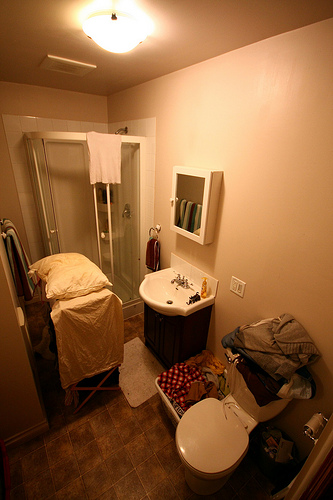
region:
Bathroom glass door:
[115, 220, 131, 258]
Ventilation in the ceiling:
[48, 58, 81, 74]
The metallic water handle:
[120, 204, 130, 220]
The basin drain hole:
[167, 298, 172, 304]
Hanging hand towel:
[146, 238, 157, 269]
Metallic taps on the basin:
[170, 271, 188, 289]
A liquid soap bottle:
[201, 278, 206, 297]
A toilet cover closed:
[187, 414, 226, 453]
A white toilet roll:
[310, 417, 323, 426]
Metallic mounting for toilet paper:
[306, 432, 315, 441]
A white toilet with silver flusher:
[175, 343, 293, 497]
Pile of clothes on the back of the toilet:
[221, 314, 321, 406]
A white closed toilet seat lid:
[175, 396, 250, 474]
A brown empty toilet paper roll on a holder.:
[304, 408, 327, 437]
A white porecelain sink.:
[138, 262, 213, 314]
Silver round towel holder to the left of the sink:
[145, 224, 162, 239]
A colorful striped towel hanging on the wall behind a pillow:
[1, 217, 40, 299]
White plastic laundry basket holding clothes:
[152, 377, 188, 427]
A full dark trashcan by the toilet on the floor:
[258, 425, 297, 481]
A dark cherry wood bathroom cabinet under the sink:
[141, 302, 212, 369]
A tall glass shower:
[22, 130, 146, 319]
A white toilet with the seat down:
[174, 345, 293, 496]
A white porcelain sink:
[140, 267, 216, 315]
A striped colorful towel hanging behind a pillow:
[2, 218, 41, 300]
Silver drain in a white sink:
[166, 299, 172, 305]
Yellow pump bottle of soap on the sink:
[200, 276, 208, 298]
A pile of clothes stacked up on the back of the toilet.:
[220, 313, 321, 406]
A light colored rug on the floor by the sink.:
[117, 335, 167, 409]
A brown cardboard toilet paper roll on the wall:
[302, 411, 325, 436]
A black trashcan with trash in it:
[255, 424, 298, 481]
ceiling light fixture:
[80, 9, 154, 54]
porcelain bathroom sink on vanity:
[138, 251, 218, 317]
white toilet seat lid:
[176, 396, 250, 475]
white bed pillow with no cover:
[27, 251, 113, 298]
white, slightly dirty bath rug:
[114, 334, 167, 407]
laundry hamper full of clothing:
[154, 348, 234, 429]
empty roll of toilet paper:
[304, 413, 324, 435]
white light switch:
[229, 275, 245, 299]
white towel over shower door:
[85, 131, 123, 184]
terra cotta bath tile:
[105, 445, 133, 484]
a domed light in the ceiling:
[80, 9, 142, 52]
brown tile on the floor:
[45, 440, 161, 490]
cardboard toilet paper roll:
[308, 413, 325, 432]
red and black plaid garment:
[155, 364, 193, 389]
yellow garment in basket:
[200, 354, 222, 370]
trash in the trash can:
[263, 432, 297, 464]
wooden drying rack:
[65, 377, 132, 406]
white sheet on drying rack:
[54, 302, 129, 371]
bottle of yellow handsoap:
[194, 274, 211, 298]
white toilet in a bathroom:
[170, 400, 247, 497]